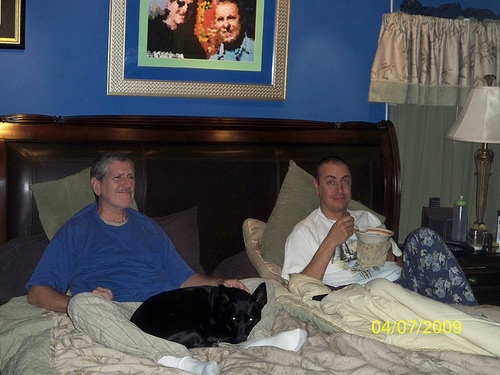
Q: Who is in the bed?
A: 2 men.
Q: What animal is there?
A: Dog.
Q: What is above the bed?
A: Picture frame.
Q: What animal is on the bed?
A: Dog.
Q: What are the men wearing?
A: Pajamas.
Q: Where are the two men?
A: On bed.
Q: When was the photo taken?
A: 4/7/2009.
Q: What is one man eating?
A: Ice cream.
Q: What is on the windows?
A: Curtains.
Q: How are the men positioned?
A: Sitting up.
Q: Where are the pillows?
A: By headrest.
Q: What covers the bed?
A: Comforter.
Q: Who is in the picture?
A: Two men.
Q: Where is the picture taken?
A: A bedroom.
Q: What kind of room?
A: A bedroom.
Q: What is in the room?
A: A bed.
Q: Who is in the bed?
A: Two men.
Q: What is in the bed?
A: A dog.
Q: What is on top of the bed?
A: A blanket.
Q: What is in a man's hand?
A: A bowl.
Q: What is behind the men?
A: Pillows.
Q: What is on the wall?
A: A photo.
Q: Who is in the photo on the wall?
A: Men smiling.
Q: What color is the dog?
A: Black.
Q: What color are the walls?
A: Blue.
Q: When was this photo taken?
A: 04/07/2009.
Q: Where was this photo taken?
A: In a bedroom.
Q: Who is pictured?
A: 2 men.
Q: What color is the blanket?
A: Tan.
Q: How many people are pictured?
A: Just 2.